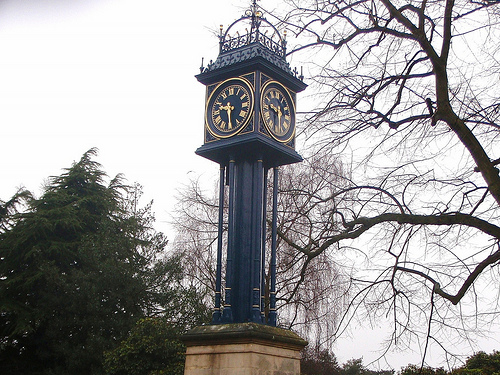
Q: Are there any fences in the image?
A: No, there are no fences.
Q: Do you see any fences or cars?
A: No, there are no fences or cars.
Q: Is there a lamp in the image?
A: No, there are no lamps.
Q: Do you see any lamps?
A: No, there are no lamps.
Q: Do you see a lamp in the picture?
A: No, there are no lamps.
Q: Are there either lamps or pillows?
A: No, there are no lamps or pillows.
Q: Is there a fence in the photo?
A: No, there are no fences.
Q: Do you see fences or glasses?
A: No, there are no fences or glasses.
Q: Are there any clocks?
A: Yes, there is a clock.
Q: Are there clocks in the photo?
A: Yes, there is a clock.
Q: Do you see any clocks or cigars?
A: Yes, there is a clock.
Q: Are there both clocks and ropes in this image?
A: No, there is a clock but no ropes.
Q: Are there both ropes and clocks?
A: No, there is a clock but no ropes.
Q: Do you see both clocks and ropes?
A: No, there is a clock but no ropes.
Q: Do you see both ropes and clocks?
A: No, there is a clock but no ropes.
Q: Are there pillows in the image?
A: No, there are no pillows.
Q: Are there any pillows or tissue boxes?
A: No, there are no pillows or tissue boxes.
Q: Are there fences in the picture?
A: No, there are no fences.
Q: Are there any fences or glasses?
A: No, there are no fences or glasses.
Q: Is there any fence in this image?
A: No, there are no fences.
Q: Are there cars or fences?
A: No, there are no fences or cars.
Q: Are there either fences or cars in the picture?
A: No, there are no fences or cars.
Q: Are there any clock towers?
A: Yes, there is a clock tower.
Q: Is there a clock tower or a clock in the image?
A: Yes, there is a clock tower.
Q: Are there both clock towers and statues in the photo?
A: No, there is a clock tower but no statues.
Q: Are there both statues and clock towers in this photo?
A: No, there is a clock tower but no statues.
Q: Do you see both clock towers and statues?
A: No, there is a clock tower but no statues.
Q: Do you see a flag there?
A: No, there are no flags.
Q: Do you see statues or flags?
A: No, there are no flags or statues.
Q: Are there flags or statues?
A: No, there are no flags or statues.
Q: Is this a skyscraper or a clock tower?
A: This is a clock tower.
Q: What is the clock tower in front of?
A: The clock tower is in front of the branches.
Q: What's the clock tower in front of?
A: The clock tower is in front of the branches.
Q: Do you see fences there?
A: No, there are no fences.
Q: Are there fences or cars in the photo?
A: No, there are no fences or cars.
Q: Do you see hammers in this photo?
A: No, there are no hammers.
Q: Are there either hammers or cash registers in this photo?
A: No, there are no hammers or cash registers.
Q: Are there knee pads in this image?
A: No, there are no knee pads.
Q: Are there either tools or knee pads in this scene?
A: No, there are no knee pads or tools.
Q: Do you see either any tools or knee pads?
A: No, there are no knee pads or tools.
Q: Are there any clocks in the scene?
A: Yes, there is a clock.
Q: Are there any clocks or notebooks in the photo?
A: Yes, there is a clock.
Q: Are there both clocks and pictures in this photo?
A: No, there is a clock but no pictures.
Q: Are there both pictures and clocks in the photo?
A: No, there is a clock but no pictures.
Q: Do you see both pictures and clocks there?
A: No, there is a clock but no pictures.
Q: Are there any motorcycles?
A: No, there are no motorcycles.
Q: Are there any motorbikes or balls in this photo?
A: No, there are no motorbikes or balls.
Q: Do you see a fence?
A: No, there are no fences.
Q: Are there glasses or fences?
A: No, there are no fences or glasses.